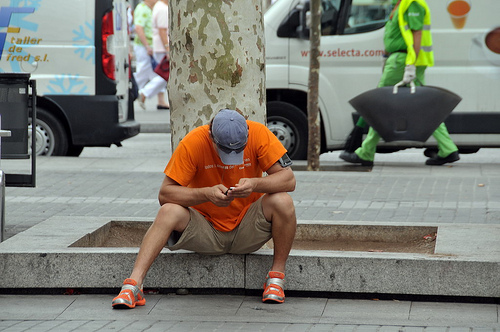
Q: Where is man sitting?
A: On the curb.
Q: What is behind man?
A: Tree trunk.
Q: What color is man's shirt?
A: Orange.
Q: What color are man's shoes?
A: Orange.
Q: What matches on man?
A: Shoes and shirt.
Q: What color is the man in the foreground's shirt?
A: Orange.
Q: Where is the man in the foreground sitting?
A: On curb.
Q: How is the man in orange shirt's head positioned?
A: Looking down.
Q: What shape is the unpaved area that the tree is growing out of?
A: Rectangle.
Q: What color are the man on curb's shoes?
A: Orange.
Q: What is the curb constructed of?
A: Concrete.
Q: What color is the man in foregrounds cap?
A: Gray.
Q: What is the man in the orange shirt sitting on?
A: Sidewalk.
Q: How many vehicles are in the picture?
A: 2.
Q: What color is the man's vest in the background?
A: Yellow.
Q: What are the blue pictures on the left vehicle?
A: Snowflakes.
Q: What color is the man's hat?
A: Blue.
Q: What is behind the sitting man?
A: Tree.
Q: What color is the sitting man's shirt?
A: Orange.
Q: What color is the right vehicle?
A: White.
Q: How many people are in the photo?
A: 4.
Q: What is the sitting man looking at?
A: His hands.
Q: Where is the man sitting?
A: On a curb.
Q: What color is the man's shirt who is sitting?
A: Orange.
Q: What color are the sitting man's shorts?
A: Khaki.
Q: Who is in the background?
A: A man in a green uniform.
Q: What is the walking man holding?
A: A black bag.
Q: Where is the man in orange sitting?
A: By the tree.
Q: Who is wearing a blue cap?
A: The man in orange.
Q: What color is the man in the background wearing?
A: Green.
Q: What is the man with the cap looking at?
A: A phone.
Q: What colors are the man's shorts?
A: Brown.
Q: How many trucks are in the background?
A: Two.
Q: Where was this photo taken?
A: Outside on the sidewalk.